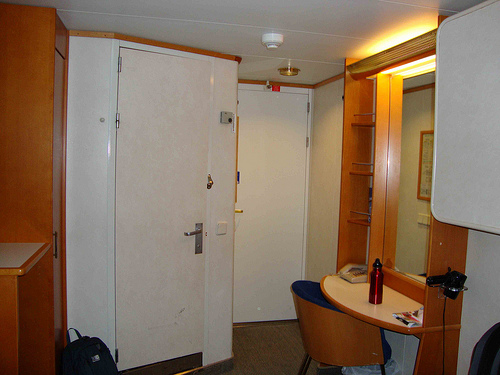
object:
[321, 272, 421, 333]
desk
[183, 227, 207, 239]
handle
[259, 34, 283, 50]
smoke detector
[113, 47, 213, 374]
door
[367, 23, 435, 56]
light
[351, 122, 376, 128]
shelf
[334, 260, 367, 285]
phone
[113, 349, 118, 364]
hinge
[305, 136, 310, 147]
hinge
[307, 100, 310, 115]
hinge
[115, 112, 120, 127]
hinge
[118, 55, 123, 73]
hinge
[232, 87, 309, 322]
door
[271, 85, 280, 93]
sticker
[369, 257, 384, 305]
water bottle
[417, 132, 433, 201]
picture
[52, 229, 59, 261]
handle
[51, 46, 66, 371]
door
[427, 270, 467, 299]
hairdryer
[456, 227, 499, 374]
wall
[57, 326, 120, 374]
backpack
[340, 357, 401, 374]
can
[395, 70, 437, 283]
mirror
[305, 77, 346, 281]
wall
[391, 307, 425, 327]
book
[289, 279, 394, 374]
chair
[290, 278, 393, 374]
blue chair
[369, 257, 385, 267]
top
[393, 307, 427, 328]
paper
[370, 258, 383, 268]
lid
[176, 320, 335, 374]
floor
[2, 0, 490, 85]
ceiling